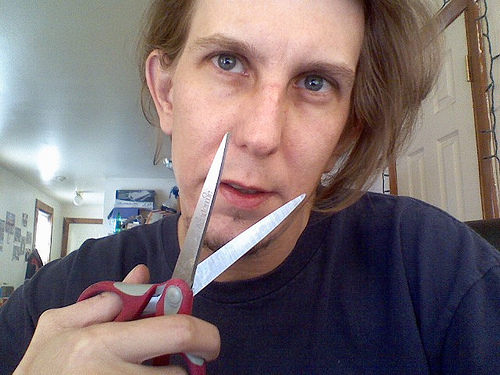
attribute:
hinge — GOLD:
[464, 54, 472, 81]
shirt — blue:
[8, 192, 497, 372]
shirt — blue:
[5, 2, 500, 372]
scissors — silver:
[75, 127, 310, 372]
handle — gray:
[81, 280, 206, 373]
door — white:
[380, 9, 484, 222]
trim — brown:
[465, 5, 498, 222]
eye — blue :
[206, 47, 248, 83]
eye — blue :
[291, 69, 338, 102]